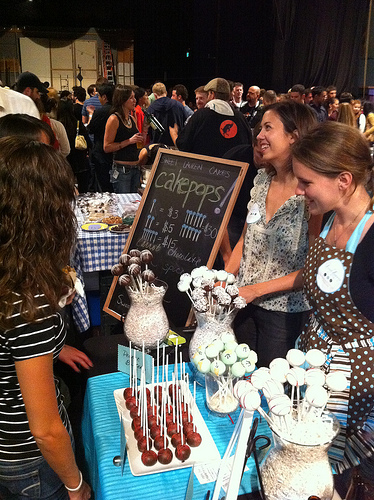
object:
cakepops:
[149, 168, 226, 214]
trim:
[156, 144, 247, 169]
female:
[218, 98, 325, 370]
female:
[289, 115, 374, 500]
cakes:
[123, 382, 205, 469]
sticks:
[189, 380, 197, 431]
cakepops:
[108, 245, 156, 287]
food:
[77, 193, 136, 233]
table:
[98, 379, 115, 431]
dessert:
[121, 337, 204, 468]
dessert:
[193, 335, 257, 421]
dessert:
[232, 345, 349, 498]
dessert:
[178, 263, 249, 386]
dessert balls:
[139, 447, 159, 468]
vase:
[259, 404, 343, 500]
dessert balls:
[226, 346, 350, 414]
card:
[115, 342, 192, 386]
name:
[119, 350, 142, 370]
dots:
[317, 303, 358, 338]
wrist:
[63, 474, 86, 496]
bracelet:
[64, 472, 85, 489]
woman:
[103, 82, 149, 194]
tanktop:
[112, 117, 138, 159]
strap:
[317, 216, 334, 240]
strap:
[343, 212, 373, 259]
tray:
[113, 379, 208, 474]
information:
[139, 178, 215, 282]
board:
[103, 147, 249, 344]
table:
[121, 194, 138, 212]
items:
[64, 172, 127, 255]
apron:
[297, 209, 374, 459]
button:
[316, 254, 347, 296]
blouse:
[234, 165, 313, 314]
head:
[2, 130, 81, 289]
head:
[290, 125, 373, 217]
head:
[258, 96, 317, 177]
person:
[191, 79, 209, 107]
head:
[200, 72, 234, 104]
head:
[148, 74, 171, 103]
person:
[140, 78, 189, 149]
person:
[14, 72, 43, 104]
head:
[15, 70, 42, 108]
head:
[301, 79, 320, 103]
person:
[321, 95, 341, 128]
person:
[287, 82, 312, 106]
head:
[286, 81, 311, 108]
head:
[255, 87, 281, 108]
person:
[245, 83, 266, 105]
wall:
[40, 47, 121, 79]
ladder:
[92, 43, 126, 87]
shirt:
[0, 273, 71, 480]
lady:
[0, 139, 92, 500]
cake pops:
[114, 338, 219, 476]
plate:
[112, 379, 222, 478]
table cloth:
[78, 379, 108, 499]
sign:
[148, 164, 227, 211]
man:
[182, 72, 254, 147]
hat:
[202, 77, 232, 98]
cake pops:
[176, 258, 248, 321]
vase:
[188, 311, 239, 389]